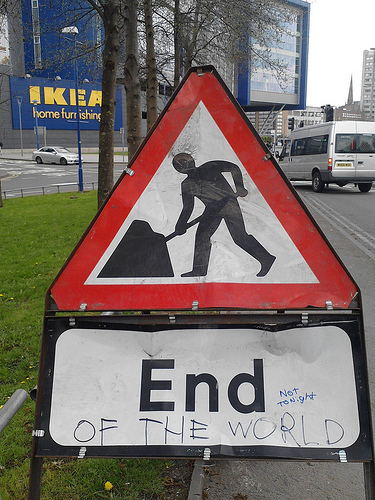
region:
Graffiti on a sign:
[59, 343, 354, 452]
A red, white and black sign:
[42, 62, 361, 314]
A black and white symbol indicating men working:
[80, 95, 325, 292]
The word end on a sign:
[41, 317, 366, 452]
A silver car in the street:
[26, 139, 86, 175]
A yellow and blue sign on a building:
[23, 77, 110, 125]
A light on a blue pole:
[56, 20, 95, 195]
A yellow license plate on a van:
[334, 158, 358, 171]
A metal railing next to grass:
[20, 177, 72, 192]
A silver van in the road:
[272, 114, 373, 196]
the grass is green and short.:
[7, 219, 53, 271]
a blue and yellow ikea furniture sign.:
[6, 76, 126, 129]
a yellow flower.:
[87, 467, 126, 495]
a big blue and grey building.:
[235, 0, 320, 117]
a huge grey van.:
[265, 115, 370, 185]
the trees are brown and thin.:
[79, 0, 301, 75]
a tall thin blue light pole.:
[60, 17, 87, 192]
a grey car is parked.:
[10, 124, 87, 172]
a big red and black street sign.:
[32, 48, 368, 318]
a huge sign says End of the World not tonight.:
[18, 35, 371, 496]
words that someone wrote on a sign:
[66, 412, 348, 453]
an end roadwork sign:
[36, 66, 373, 468]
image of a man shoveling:
[94, 146, 283, 282]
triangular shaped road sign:
[53, 61, 364, 310]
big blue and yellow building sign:
[10, 3, 122, 134]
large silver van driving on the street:
[270, 123, 370, 191]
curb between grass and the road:
[181, 457, 213, 498]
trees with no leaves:
[82, 0, 272, 247]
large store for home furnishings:
[0, 1, 319, 151]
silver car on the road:
[25, 143, 78, 166]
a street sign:
[31, 62, 371, 492]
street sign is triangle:
[40, 65, 373, 322]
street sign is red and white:
[37, 55, 373, 322]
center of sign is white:
[39, 54, 371, 316]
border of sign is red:
[39, 50, 365, 321]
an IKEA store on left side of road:
[3, 3, 359, 299]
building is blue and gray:
[4, 0, 310, 111]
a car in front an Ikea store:
[21, 80, 114, 174]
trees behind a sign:
[17, 0, 365, 480]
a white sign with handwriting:
[30, 312, 371, 474]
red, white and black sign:
[113, 115, 273, 261]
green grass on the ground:
[111, 463, 137, 483]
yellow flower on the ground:
[92, 474, 122, 499]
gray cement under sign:
[250, 467, 300, 493]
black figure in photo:
[116, 133, 254, 286]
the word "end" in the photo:
[134, 350, 276, 422]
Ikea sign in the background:
[27, 76, 108, 144]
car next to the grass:
[284, 101, 363, 173]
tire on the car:
[305, 167, 335, 193]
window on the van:
[288, 133, 338, 161]